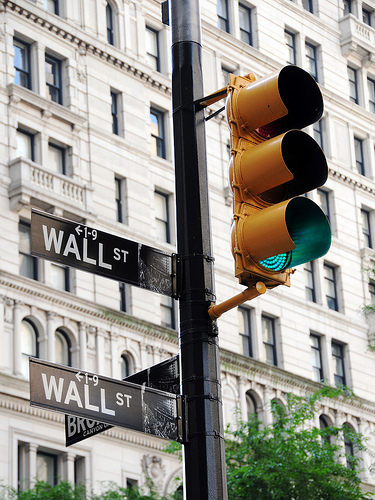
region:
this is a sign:
[23, 207, 179, 293]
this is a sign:
[21, 356, 177, 454]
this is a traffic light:
[239, 201, 340, 284]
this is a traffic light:
[242, 132, 327, 187]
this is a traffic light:
[213, 49, 345, 126]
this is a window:
[253, 308, 288, 371]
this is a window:
[108, 164, 130, 225]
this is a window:
[147, 103, 171, 166]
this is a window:
[105, 85, 120, 140]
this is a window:
[327, 329, 355, 384]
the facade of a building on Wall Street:
[2, 1, 373, 464]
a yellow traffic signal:
[193, 54, 348, 315]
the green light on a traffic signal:
[239, 194, 333, 290]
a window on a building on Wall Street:
[12, 33, 37, 90]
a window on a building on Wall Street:
[330, 336, 356, 394]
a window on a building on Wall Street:
[309, 328, 324, 384]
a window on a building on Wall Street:
[263, 309, 282, 369]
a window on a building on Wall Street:
[236, 302, 260, 358]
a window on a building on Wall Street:
[18, 219, 37, 278]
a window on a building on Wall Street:
[17, 123, 40, 163]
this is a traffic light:
[242, 72, 320, 125]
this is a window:
[282, 26, 298, 67]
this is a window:
[345, 61, 364, 108]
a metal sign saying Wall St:
[27, 353, 188, 445]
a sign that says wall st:
[26, 206, 191, 303]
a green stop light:
[217, 198, 335, 297]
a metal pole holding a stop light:
[157, 1, 228, 499]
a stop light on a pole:
[193, 62, 332, 320]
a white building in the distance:
[0, 0, 374, 499]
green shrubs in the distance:
[224, 373, 371, 499]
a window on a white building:
[309, 325, 355, 395]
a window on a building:
[306, 322, 357, 395]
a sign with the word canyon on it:
[44, 352, 186, 447]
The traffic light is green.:
[238, 198, 318, 276]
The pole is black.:
[156, 14, 248, 442]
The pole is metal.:
[160, 16, 218, 425]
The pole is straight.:
[166, 28, 243, 427]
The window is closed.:
[6, 23, 40, 103]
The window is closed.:
[39, 42, 78, 107]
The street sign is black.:
[26, 355, 176, 440]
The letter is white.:
[37, 369, 63, 403]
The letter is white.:
[66, 378, 79, 409]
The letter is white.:
[81, 382, 98, 417]